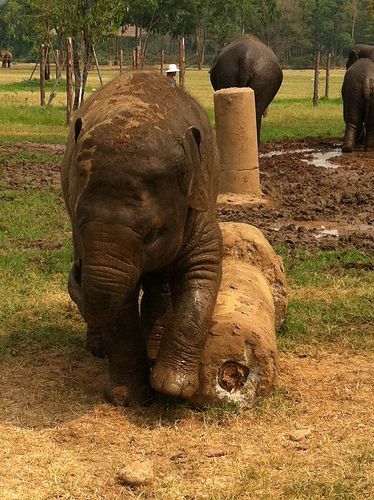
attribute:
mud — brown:
[207, 137, 373, 257]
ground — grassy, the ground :
[2, 61, 373, 499]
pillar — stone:
[208, 84, 269, 207]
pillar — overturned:
[201, 218, 288, 400]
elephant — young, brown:
[61, 70, 222, 415]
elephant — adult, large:
[209, 31, 283, 154]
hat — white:
[166, 62, 181, 75]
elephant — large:
[2, 48, 16, 70]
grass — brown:
[1, 348, 373, 500]